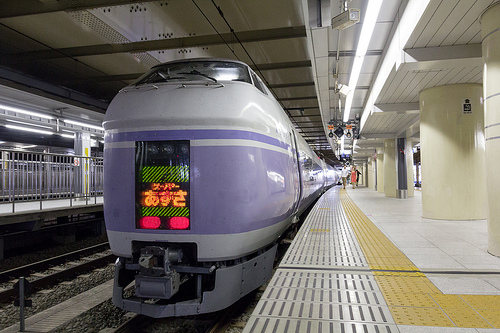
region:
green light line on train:
[141, 163, 147, 173]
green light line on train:
[140, 163, 158, 183]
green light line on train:
[153, 164, 175, 182]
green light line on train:
[139, 204, 146, 214]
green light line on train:
[174, 206, 186, 215]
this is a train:
[31, 68, 240, 268]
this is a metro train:
[86, 72, 276, 257]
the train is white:
[123, 96, 260, 280]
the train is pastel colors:
[125, 72, 340, 312]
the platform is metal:
[305, 239, 373, 317]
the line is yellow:
[354, 234, 420, 316]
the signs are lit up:
[119, 154, 232, 269]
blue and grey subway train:
[89, 48, 364, 315]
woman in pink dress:
[348, 163, 360, 188]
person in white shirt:
[340, 165, 350, 188]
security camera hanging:
[319, 3, 374, 38]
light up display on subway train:
[118, 133, 202, 240]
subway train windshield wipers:
[136, 68, 233, 94]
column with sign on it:
[445, 80, 487, 227]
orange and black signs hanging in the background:
[323, 108, 365, 138]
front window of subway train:
[128, 52, 277, 104]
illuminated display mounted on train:
[135, 140, 191, 231]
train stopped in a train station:
[100, 62, 360, 319]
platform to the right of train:
[241, 174, 498, 331]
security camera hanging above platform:
[330, 1, 361, 31]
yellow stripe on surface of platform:
[337, 184, 497, 327]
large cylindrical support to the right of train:
[418, 85, 485, 221]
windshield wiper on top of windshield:
[174, 69, 220, 86]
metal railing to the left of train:
[0, 147, 106, 214]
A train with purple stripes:
[100, 57, 352, 318]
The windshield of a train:
[128, 63, 270, 95]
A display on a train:
[135, 139, 190, 230]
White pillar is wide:
[418, 86, 485, 218]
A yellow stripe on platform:
[336, 183, 498, 327]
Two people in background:
[339, 163, 359, 190]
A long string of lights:
[343, 0, 383, 122]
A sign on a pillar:
[461, 95, 471, 112]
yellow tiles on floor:
[338, 193, 439, 331]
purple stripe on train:
[109, 126, 336, 241]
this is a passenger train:
[72, 85, 344, 322]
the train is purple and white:
[105, 103, 311, 306]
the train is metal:
[122, 93, 272, 210]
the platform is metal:
[282, 189, 365, 304]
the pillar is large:
[374, 97, 476, 219]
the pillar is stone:
[387, 122, 457, 227]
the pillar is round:
[404, 101, 495, 254]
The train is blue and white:
[57, 27, 364, 315]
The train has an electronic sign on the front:
[56, 12, 316, 317]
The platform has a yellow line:
[315, 158, 439, 318]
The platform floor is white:
[290, 175, 499, 294]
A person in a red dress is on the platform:
[325, 156, 377, 209]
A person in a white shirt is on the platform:
[331, 162, 351, 194]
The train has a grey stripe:
[80, 71, 330, 307]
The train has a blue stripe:
[87, 101, 351, 225]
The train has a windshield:
[99, 43, 308, 192]